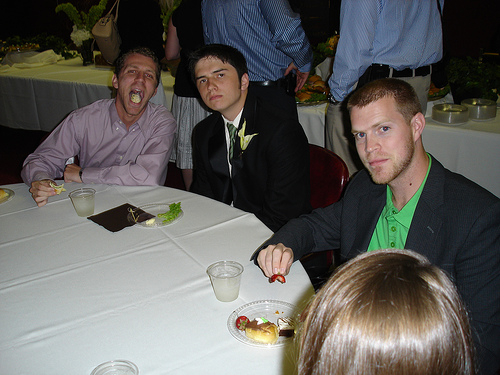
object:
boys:
[19, 47, 175, 207]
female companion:
[276, 246, 480, 375]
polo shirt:
[366, 153, 432, 255]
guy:
[252, 77, 500, 375]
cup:
[205, 261, 244, 303]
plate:
[227, 300, 302, 348]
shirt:
[362, 181, 419, 260]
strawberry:
[235, 315, 250, 331]